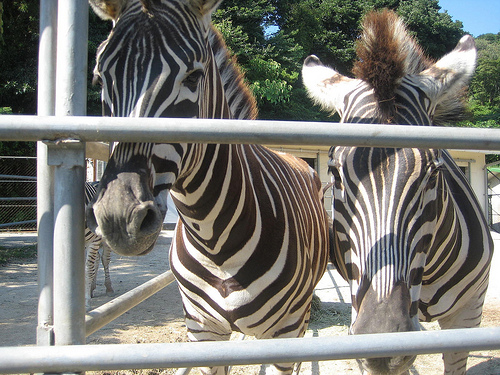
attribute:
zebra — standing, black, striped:
[301, 8, 499, 374]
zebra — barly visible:
[83, 182, 115, 296]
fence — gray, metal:
[0, 1, 500, 374]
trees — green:
[1, 0, 500, 130]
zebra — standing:
[91, 1, 327, 373]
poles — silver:
[1, 2, 499, 374]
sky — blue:
[0, 0, 499, 35]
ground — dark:
[0, 181, 500, 364]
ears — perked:
[296, 33, 481, 110]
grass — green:
[0, 234, 48, 268]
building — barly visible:
[77, 135, 491, 227]